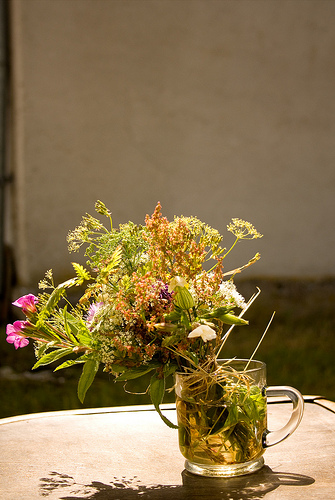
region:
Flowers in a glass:
[30, 186, 299, 398]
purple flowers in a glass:
[9, 292, 51, 362]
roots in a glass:
[176, 359, 264, 469]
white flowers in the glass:
[174, 255, 245, 311]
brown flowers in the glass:
[139, 207, 217, 291]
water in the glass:
[173, 395, 274, 463]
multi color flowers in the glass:
[61, 222, 302, 452]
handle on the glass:
[249, 366, 310, 445]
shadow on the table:
[45, 459, 316, 499]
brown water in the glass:
[175, 397, 261, 472]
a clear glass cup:
[174, 351, 301, 476]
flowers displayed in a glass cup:
[1, 198, 303, 478]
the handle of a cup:
[262, 385, 303, 446]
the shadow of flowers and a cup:
[40, 469, 314, 498]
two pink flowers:
[0, 293, 40, 346]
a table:
[0, 394, 333, 499]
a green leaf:
[74, 353, 100, 403]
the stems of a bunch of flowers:
[174, 360, 267, 455]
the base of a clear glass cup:
[182, 456, 266, 475]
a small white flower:
[189, 322, 216, 343]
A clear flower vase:
[174, 364, 306, 472]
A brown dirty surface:
[15, 434, 78, 498]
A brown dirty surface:
[77, 412, 141, 489]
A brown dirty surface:
[279, 444, 333, 498]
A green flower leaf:
[151, 375, 185, 436]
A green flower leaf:
[79, 352, 97, 430]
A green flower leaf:
[55, 263, 90, 324]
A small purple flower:
[5, 317, 26, 345]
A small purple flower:
[12, 294, 45, 314]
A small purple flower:
[81, 305, 112, 329]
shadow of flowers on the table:
[35, 456, 172, 498]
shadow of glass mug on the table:
[183, 468, 310, 496]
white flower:
[186, 317, 216, 348]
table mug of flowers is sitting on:
[1, 387, 333, 497]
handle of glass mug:
[269, 376, 307, 445]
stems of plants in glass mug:
[178, 368, 265, 459]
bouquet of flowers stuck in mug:
[10, 187, 259, 401]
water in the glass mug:
[176, 396, 259, 460]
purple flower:
[151, 278, 179, 304]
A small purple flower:
[144, 276, 177, 319]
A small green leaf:
[78, 359, 100, 400]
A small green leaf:
[147, 373, 174, 433]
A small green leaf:
[217, 310, 251, 329]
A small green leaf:
[127, 353, 155, 395]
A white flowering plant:
[223, 208, 251, 247]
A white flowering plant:
[224, 274, 249, 323]